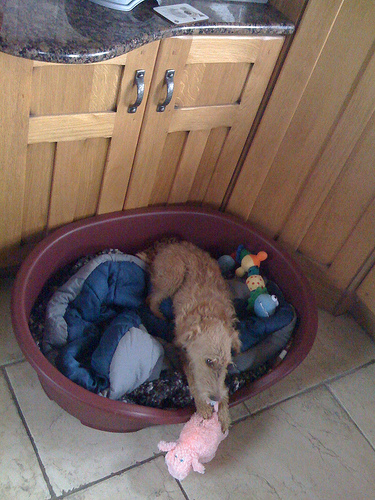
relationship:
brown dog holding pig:
[144, 235, 243, 433] [157, 400, 229, 480]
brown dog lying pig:
[144, 235, 243, 433] [157, 400, 229, 480]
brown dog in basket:
[144, 235, 243, 433] [8, 197, 320, 446]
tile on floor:
[326, 360, 373, 458] [3, 274, 371, 497]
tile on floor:
[180, 386, 373, 498] [3, 274, 371, 497]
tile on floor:
[243, 308, 373, 413] [3, 274, 371, 497]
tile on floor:
[59, 447, 188, 498] [3, 274, 371, 497]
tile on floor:
[4, 355, 193, 498] [3, 274, 371, 497]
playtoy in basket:
[234, 250, 279, 320] [8, 193, 328, 423]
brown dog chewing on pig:
[144, 235, 243, 433] [157, 400, 229, 480]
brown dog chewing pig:
[107, 219, 254, 303] [157, 400, 229, 480]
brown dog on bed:
[144, 235, 243, 433] [42, 254, 298, 402]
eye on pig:
[178, 457, 184, 462] [157, 400, 229, 480]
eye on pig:
[173, 452, 178, 458] [157, 400, 229, 480]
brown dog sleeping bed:
[144, 235, 243, 433] [42, 254, 298, 402]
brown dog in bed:
[144, 235, 243, 433] [22, 259, 284, 406]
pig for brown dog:
[157, 400, 229, 480] [144, 235, 243, 433]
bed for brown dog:
[42, 254, 298, 402] [144, 235, 243, 433]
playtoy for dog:
[219, 244, 278, 320] [149, 253, 241, 348]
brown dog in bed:
[144, 235, 243, 433] [6, 201, 322, 435]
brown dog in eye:
[144, 235, 243, 433] [204, 354, 215, 366]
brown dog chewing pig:
[144, 235, 243, 433] [157, 400, 229, 480]